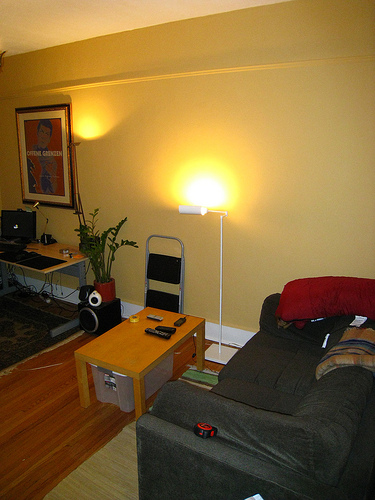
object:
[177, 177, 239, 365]
lamp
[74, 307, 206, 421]
coffee table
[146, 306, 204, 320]
edge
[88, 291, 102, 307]
speaker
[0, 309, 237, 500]
floor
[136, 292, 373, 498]
black couch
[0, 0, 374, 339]
wall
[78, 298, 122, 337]
speaker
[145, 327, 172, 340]
remote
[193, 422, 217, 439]
tape measure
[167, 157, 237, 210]
light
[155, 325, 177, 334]
remote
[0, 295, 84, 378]
carpet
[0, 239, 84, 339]
desk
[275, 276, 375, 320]
blanket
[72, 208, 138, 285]
plant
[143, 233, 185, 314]
ladder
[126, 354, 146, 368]
part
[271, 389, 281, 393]
part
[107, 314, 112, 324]
part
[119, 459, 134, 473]
part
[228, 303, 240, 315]
part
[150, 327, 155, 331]
part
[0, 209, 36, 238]
tv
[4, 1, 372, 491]
room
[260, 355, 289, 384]
part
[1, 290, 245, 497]
ground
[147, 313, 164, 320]
remote